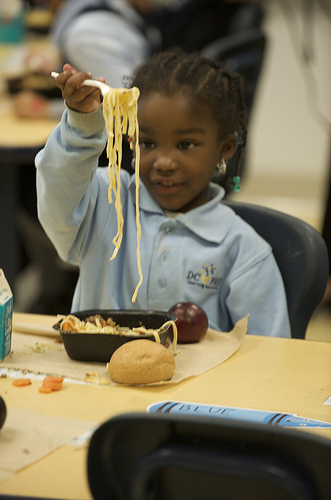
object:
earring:
[216, 158, 226, 175]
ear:
[218, 131, 239, 164]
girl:
[34, 49, 293, 337]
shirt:
[34, 98, 291, 338]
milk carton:
[0, 268, 14, 362]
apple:
[168, 301, 209, 343]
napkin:
[0, 311, 251, 388]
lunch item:
[56, 313, 181, 354]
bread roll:
[108, 339, 176, 385]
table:
[0, 311, 331, 500]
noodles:
[102, 85, 143, 302]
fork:
[51, 71, 138, 107]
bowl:
[52, 308, 179, 363]